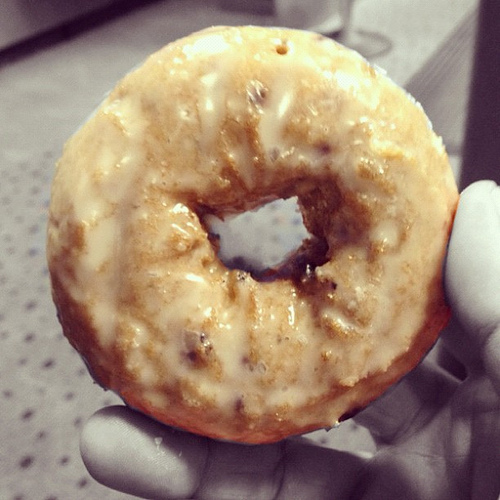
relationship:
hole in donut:
[203, 195, 315, 270] [47, 25, 459, 446]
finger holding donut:
[80, 405, 373, 499] [47, 25, 459, 446]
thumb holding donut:
[442, 180, 500, 394] [47, 25, 459, 446]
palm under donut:
[351, 375, 500, 498] [47, 25, 459, 446]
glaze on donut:
[47, 26, 460, 445] [47, 25, 459, 446]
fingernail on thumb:
[491, 186, 499, 215] [442, 180, 500, 394]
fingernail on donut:
[491, 186, 499, 215] [47, 25, 459, 446]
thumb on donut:
[442, 180, 500, 394] [47, 25, 459, 446]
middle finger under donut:
[206, 216, 464, 450] [47, 25, 459, 446]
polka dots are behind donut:
[0, 147, 360, 499] [47, 25, 459, 446]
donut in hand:
[47, 25, 459, 446] [80, 179, 500, 498]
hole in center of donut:
[203, 195, 315, 270] [47, 25, 459, 446]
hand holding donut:
[80, 179, 500, 498] [47, 25, 459, 446]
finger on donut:
[80, 405, 373, 499] [47, 25, 459, 446]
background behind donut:
[0, 1, 499, 499] [47, 25, 459, 446]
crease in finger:
[187, 438, 211, 499] [80, 405, 373, 499]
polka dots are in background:
[0, 147, 360, 499] [0, 1, 499, 499]